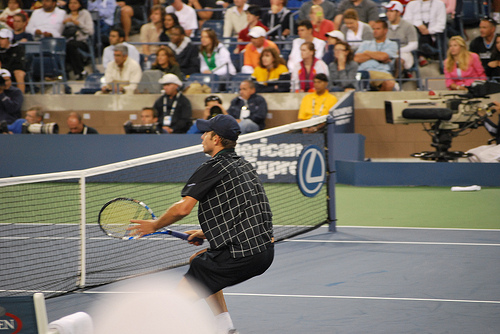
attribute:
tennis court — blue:
[9, 149, 464, 302]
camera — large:
[371, 81, 497, 160]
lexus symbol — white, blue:
[293, 141, 325, 199]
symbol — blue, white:
[281, 151, 338, 205]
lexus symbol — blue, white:
[291, 146, 326, 197]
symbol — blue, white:
[290, 142, 329, 201]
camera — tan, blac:
[377, 83, 499, 165]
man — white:
[138, 117, 279, 324]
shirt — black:
[183, 160, 270, 257]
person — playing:
[164, 119, 331, 326]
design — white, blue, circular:
[295, 143, 327, 195]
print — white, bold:
[240, 139, 306, 181]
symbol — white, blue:
[296, 147, 327, 199]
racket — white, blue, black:
[93, 191, 200, 247]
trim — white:
[2, 113, 329, 198]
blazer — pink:
[442, 50, 484, 90]